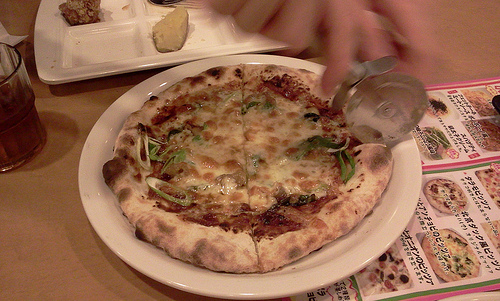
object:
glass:
[1, 37, 51, 177]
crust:
[170, 228, 317, 282]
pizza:
[102, 62, 394, 273]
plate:
[77, 53, 425, 300]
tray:
[33, 0, 312, 84]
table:
[1, 0, 499, 300]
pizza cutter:
[310, 38, 428, 147]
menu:
[273, 74, 499, 300]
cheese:
[146, 79, 351, 236]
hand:
[208, 1, 437, 100]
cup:
[0, 41, 47, 174]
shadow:
[11, 110, 78, 170]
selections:
[358, 166, 499, 299]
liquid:
[0, 73, 45, 168]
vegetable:
[338, 148, 356, 183]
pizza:
[424, 177, 468, 216]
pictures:
[410, 80, 499, 165]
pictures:
[417, 209, 489, 284]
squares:
[64, 16, 142, 67]